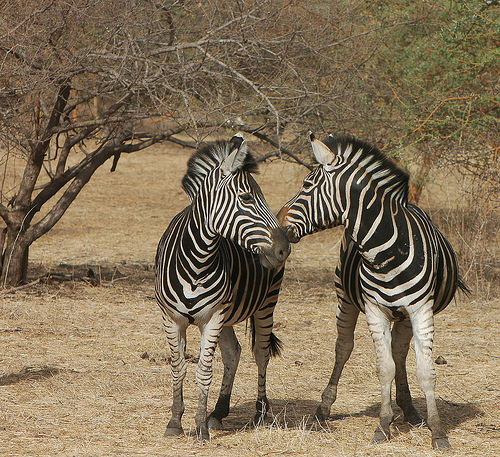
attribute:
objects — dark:
[68, 258, 120, 287]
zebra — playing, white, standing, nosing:
[156, 135, 288, 444]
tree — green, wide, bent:
[4, 2, 495, 286]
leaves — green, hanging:
[7, 5, 496, 158]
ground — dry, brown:
[0, 153, 493, 456]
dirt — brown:
[9, 273, 498, 456]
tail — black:
[245, 321, 283, 357]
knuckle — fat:
[162, 427, 211, 441]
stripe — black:
[169, 229, 247, 314]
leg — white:
[165, 314, 223, 435]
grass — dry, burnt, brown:
[7, 293, 499, 455]